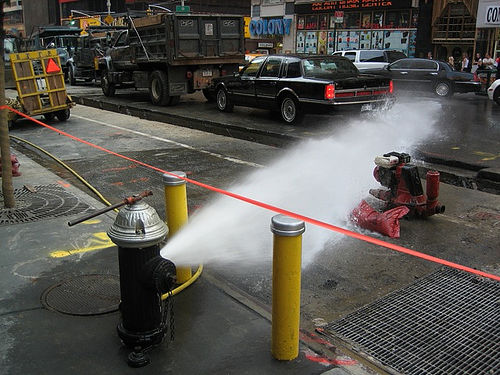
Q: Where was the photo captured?
A: City street.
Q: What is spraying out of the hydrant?
A: Water.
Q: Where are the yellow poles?
A: Besides hydrant.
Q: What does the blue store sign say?
A: Colony.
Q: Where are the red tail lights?
A: On black car.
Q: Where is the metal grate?
A: On street.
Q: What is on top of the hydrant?
A: Silver cap.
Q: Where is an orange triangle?
A: On yellow truck.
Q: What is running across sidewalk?
A: Orange tape.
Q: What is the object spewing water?
A: Fire hydrant.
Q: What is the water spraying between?
A: Two posts.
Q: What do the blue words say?
A: Colony.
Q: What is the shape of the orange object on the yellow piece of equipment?
A: Triangle.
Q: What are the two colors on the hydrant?
A: Black and silver.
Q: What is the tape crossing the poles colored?
A: Orange.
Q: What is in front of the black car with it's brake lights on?
A: A dump truck.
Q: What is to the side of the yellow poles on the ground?
A: Metal grates.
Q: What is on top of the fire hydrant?
A: A wrench.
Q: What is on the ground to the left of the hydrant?
A: A manhole cover.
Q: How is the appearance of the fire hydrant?
A: Water is gushing from it.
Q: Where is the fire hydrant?
A: On the sidewalk by a busy street in a city.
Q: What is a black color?
A: A car.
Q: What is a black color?
A: A fire hydrant.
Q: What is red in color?
A: Tape.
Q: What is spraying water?
A: A hydrant.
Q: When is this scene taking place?
A: Daytime.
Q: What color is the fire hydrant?
A: Black and silver.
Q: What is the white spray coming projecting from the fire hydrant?
A: Water.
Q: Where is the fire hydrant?
A: Sidewalk.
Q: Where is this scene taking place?
A: In a city.